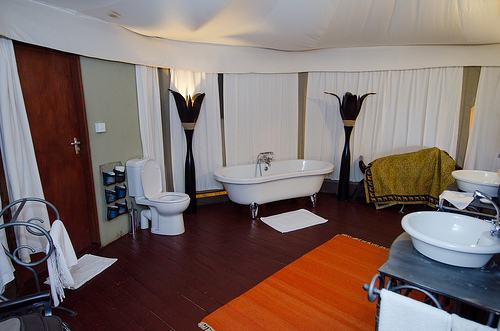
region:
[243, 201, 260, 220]
silver pedestal on tub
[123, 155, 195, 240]
solid white toilet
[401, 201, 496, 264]
solid white bowl sink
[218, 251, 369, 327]
orange rug with fringe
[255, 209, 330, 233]
solid white bath rug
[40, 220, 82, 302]
solid white bath towel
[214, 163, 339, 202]
solid white bath tub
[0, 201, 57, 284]
ornate silver towel holder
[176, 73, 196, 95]
reflection of light on curtain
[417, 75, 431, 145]
wrinkle in white curtain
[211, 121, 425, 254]
a clawfoot bathtub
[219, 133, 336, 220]
a bathroom with a tub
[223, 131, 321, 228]
a bathroom with a white tub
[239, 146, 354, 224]
a tub in the bathroom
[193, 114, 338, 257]
a tub that is white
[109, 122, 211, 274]
a toilet in the bathroom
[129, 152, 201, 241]
a white toilet in the bathroom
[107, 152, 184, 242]
a bathroom toilet that is white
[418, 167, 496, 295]
a white bathroom sink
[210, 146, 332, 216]
a white claw tub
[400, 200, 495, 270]
a white porclean sink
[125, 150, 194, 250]
a white toilet with the seat open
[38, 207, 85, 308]
a white towel hanging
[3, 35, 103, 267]
a brown wooden door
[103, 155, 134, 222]
toilet paper in mesh containers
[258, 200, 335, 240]
a white bath mat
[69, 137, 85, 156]
a silver door handle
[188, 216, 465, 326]
an orange rug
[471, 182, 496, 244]
a silver sink faucet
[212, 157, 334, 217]
a white porcelain bath tub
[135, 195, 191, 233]
a white porcelain toilet bowl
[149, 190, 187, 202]
a white plastic toilet seat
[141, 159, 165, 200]
a white plastic toilet lid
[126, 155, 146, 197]
a white porcelain toilet tank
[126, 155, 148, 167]
a white porcelain toilet tank lid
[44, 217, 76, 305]
a hanging white towel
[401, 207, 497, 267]
a white porcelain bathroom sink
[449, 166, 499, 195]
a white porcelain bathroom sink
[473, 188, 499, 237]
a chrome bathroom sink faucet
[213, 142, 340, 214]
A white tub on a wooden floor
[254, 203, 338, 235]
A towel on a wooden floor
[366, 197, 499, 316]
A white sink on a stand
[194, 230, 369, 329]
An orange rug on a wooden floor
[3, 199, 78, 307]
A white towel hanging on a towel rack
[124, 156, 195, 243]
A toilet sitting on a wooden floor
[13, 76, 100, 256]
A brown wooden door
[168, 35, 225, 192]
A large floor lamp in front of long white curtain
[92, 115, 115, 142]
Electric thermostat hanging on wall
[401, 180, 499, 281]
A sink with a silver faucet